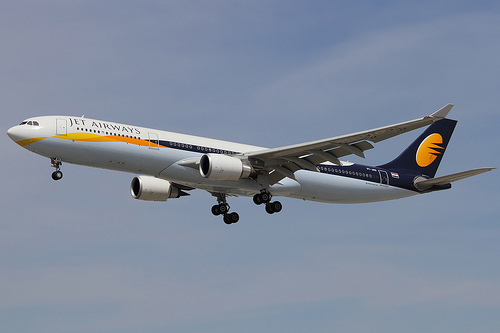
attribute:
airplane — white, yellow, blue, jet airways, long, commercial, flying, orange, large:
[6, 100, 494, 229]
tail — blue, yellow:
[388, 110, 493, 202]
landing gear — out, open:
[208, 184, 288, 228]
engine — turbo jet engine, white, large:
[193, 149, 260, 182]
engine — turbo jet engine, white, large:
[129, 170, 190, 207]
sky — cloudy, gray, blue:
[3, 2, 497, 330]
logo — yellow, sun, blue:
[409, 128, 447, 168]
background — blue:
[407, 115, 459, 179]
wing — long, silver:
[236, 102, 457, 182]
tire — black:
[208, 201, 241, 227]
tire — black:
[248, 188, 283, 215]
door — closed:
[51, 114, 72, 141]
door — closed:
[372, 167, 394, 189]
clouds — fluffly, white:
[3, 2, 498, 327]